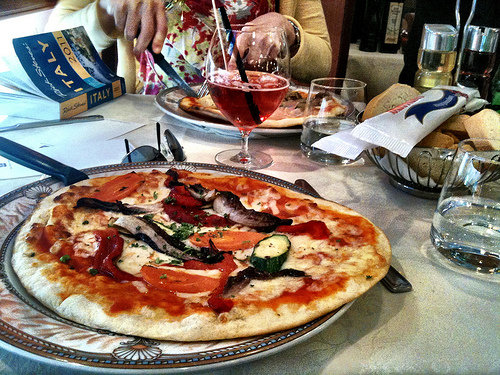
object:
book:
[0, 24, 127, 119]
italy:
[36, 41, 88, 94]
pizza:
[5, 152, 398, 360]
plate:
[0, 155, 380, 374]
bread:
[462, 108, 500, 152]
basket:
[360, 138, 500, 199]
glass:
[298, 74, 370, 168]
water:
[296, 116, 366, 153]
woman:
[37, 0, 335, 98]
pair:
[100, 95, 205, 173]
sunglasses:
[112, 122, 187, 168]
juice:
[204, 74, 287, 131]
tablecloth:
[0, 91, 499, 374]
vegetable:
[244, 232, 294, 277]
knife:
[131, 27, 199, 100]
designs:
[5, 187, 30, 235]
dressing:
[455, 19, 497, 100]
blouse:
[129, 0, 305, 96]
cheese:
[108, 234, 184, 277]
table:
[0, 84, 499, 374]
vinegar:
[454, 51, 496, 89]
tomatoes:
[140, 262, 222, 293]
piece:
[238, 225, 295, 271]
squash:
[275, 212, 340, 242]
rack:
[417, 18, 463, 55]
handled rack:
[449, 0, 480, 87]